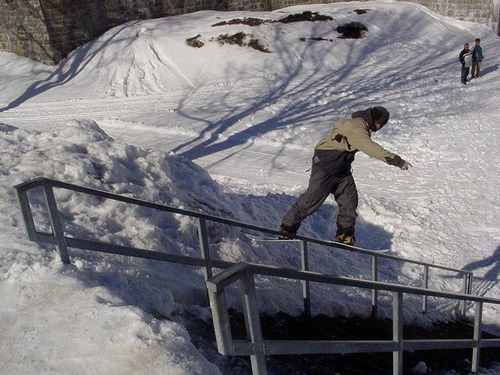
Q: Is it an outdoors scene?
A: Yes, it is outdoors.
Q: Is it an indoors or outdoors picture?
A: It is outdoors.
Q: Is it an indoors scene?
A: No, it is outdoors.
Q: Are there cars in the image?
A: No, there are no cars.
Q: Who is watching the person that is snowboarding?
A: The people are watching the man.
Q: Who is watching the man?
A: The people are watching the man.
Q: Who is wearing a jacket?
A: The people are wearing a jacket.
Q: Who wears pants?
A: The people wear pants.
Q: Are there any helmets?
A: No, there are no helmets.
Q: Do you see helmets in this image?
A: No, there are no helmets.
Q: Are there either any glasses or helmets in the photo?
A: No, there are no helmets or glasses.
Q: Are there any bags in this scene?
A: No, there are no bags.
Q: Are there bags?
A: No, there are no bags.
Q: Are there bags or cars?
A: No, there are no bags or cars.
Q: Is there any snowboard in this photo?
A: Yes, there is a snowboard.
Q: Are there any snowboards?
A: Yes, there is a snowboard.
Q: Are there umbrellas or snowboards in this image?
A: Yes, there is a snowboard.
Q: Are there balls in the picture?
A: No, there are no balls.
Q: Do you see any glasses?
A: No, there are no glasses.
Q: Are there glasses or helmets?
A: No, there are no glasses or helmets.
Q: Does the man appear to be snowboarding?
A: Yes, the man is snowboarding.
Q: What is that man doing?
A: The man is snowboarding.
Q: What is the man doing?
A: The man is snowboarding.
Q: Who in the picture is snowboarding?
A: The man is snowboarding.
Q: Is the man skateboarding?
A: No, the man is snowboarding.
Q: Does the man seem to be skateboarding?
A: No, the man is snowboarding.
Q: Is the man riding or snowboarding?
A: The man is snowboarding.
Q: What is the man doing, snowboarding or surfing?
A: The man is snowboarding.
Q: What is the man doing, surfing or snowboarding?
A: The man is snowboarding.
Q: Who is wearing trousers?
A: The man is wearing trousers.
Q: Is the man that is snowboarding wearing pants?
A: Yes, the man is wearing pants.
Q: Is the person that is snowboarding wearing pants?
A: Yes, the man is wearing pants.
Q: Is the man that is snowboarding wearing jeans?
A: No, the man is wearing pants.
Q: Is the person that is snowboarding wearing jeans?
A: No, the man is wearing pants.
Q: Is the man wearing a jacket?
A: Yes, the man is wearing a jacket.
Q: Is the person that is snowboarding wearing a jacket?
A: Yes, the man is wearing a jacket.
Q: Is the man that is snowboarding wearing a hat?
A: No, the man is wearing a jacket.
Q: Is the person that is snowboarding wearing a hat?
A: No, the man is wearing a jacket.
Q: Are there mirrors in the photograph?
A: No, there are no mirrors.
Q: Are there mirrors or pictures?
A: No, there are no mirrors or pictures.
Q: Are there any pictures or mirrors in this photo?
A: No, there are no mirrors or pictures.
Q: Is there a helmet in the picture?
A: No, there are no helmets.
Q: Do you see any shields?
A: No, there are no shields.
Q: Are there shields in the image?
A: No, there are no shields.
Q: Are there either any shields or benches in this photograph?
A: No, there are no shields or benches.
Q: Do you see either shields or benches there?
A: No, there are no shields or benches.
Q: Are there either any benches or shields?
A: No, there are no shields or benches.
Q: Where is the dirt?
A: The dirt is on the hill.